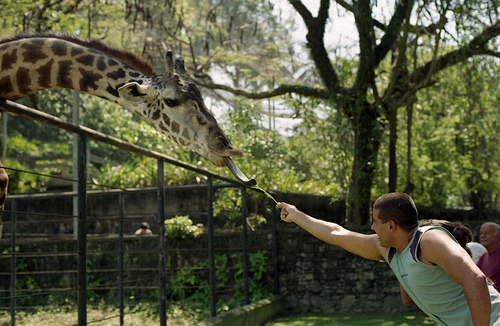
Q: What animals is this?
A: Giraffe.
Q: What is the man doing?
A: Stretching.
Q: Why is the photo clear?
A: Its during the day.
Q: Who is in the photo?
A: People.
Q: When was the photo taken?
A: Daytime.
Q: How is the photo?
A: Clear.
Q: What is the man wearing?
A: Clothes.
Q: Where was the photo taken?
A: The zoo.